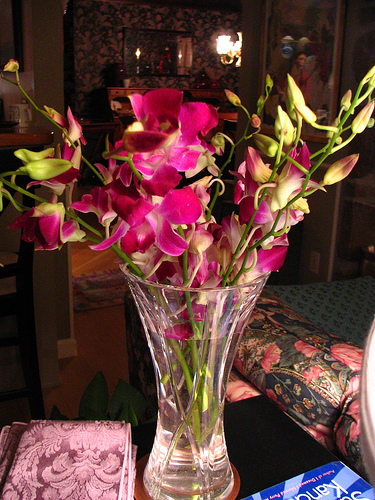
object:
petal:
[152, 185, 202, 224]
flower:
[5, 200, 72, 255]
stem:
[178, 226, 201, 377]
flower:
[86, 186, 203, 256]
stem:
[2, 169, 183, 344]